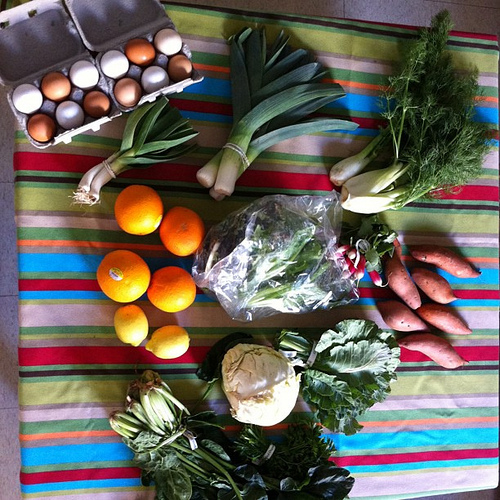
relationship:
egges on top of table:
[9, 28, 195, 143] [11, 1, 500, 498]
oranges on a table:
[96, 182, 206, 312] [11, 1, 500, 498]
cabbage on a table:
[220, 340, 302, 426] [11, 1, 500, 498]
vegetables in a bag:
[214, 199, 332, 322] [188, 191, 362, 322]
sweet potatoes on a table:
[376, 229, 482, 372] [11, 1, 500, 498]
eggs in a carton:
[9, 28, 195, 143] [1, 0, 205, 152]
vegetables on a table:
[70, 9, 500, 500] [11, 1, 500, 498]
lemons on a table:
[113, 304, 193, 361] [11, 1, 500, 498]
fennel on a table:
[196, 26, 362, 201] [11, 1, 500, 498]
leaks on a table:
[74, 96, 202, 206] [11, 1, 500, 498]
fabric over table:
[7, 4, 499, 496] [11, 1, 500, 498]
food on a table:
[8, 6, 485, 498] [11, 1, 500, 498]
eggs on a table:
[9, 28, 195, 143] [11, 1, 500, 498]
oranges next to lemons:
[96, 182, 206, 312] [113, 304, 193, 361]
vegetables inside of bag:
[214, 199, 332, 322] [188, 191, 362, 322]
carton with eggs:
[1, 0, 205, 152] [9, 28, 195, 143]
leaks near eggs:
[74, 96, 202, 206] [9, 28, 195, 143]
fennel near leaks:
[196, 26, 362, 201] [74, 96, 202, 206]